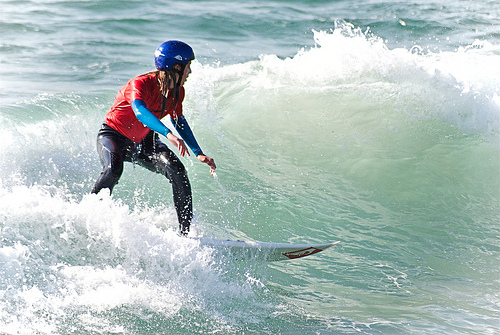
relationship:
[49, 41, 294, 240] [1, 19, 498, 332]
woman riding wave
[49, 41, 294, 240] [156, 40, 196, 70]
woman wearing helmet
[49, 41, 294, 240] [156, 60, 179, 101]
woman has hair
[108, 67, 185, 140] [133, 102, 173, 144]
t-shirt with sleeve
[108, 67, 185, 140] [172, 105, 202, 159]
t-shirt with sleeve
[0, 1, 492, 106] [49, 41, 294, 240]
water behind woman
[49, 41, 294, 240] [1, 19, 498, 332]
woman on wave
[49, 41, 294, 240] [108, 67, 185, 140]
woman in t-shirt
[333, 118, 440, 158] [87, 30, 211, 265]
waves roll toward surfer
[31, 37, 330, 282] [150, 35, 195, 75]
surfer wearing helmet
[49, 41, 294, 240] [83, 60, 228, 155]
woman wears shirt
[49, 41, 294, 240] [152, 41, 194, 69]
woman has helmet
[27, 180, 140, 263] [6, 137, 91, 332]
waves in water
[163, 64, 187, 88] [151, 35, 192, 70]
strap securing helmet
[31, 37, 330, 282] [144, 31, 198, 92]
surfer has head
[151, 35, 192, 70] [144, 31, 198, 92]
helmet attached to head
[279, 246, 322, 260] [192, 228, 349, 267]
logo on surfboard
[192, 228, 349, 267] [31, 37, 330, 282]
surfboard supporting surfer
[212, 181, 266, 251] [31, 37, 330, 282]
water drips from surfer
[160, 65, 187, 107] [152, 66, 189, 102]
sticks on neck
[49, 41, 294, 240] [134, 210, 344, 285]
woman using surfboard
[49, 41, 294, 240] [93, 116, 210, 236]
woman has black pants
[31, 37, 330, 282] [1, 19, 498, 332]
surfer on water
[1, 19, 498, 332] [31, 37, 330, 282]
water around surfer